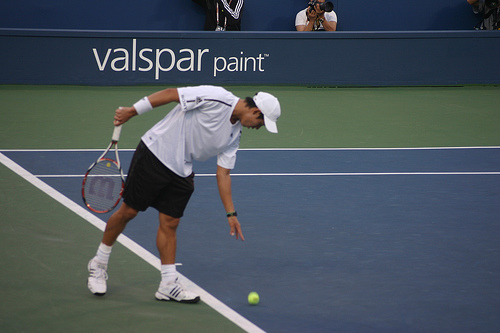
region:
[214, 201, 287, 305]
player bouncing wall on court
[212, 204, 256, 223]
black watch on player's hand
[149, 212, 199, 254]
bulges in man's foot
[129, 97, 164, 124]
white wrist band on hand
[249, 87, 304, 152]
white cap on head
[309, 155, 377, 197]
lines at side of tennis court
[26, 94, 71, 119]
green color on the pavement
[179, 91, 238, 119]
black stripe on white tee shirt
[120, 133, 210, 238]
player wearing black shorts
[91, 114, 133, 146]
white grip on tennis racket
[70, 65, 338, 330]
man bending for ball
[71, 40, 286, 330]
man holding a racket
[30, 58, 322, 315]
man wearing a cap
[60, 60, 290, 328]
man wearing a white shirt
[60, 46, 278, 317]
man wearing black shorts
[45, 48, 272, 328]
man wearing white socks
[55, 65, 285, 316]
man wearing white shoes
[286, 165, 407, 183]
white line on tennis court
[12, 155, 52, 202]
white line on tennis court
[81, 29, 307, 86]
sign in a tennis court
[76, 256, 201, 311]
THE MAN IS WEARING WHITE SHOES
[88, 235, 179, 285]
THE MAN IS WEARING WHITE SOCKS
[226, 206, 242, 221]
THE MAN IS WEARING A WATCH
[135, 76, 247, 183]
THE MAN IS WEARING A WHITE SHIRT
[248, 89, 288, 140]
THE MAN IS WEARING A WHITE HAT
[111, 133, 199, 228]
THE MAN IS WEARING BLACK SHORTS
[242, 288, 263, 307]
THE TENNIS BALL IS YELLOW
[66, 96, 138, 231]
THE MAN IS HOLDING A RACKET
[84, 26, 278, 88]
THE ADVERTISEMENT IS ON THE BLUE WALL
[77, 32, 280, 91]
THE ADVERTISEMENT READS VALSPAR PAINT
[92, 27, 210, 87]
A word "valspar" printed on the side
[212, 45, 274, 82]
A word "paint" printed on the side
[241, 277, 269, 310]
A small tennis ball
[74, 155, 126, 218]
The bottom portion of a tennis racket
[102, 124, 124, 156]
The top portion of a tennis racket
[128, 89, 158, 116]
A white wrist band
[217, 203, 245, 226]
A green wrist band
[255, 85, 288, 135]
A white cap on the helmet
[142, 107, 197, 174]
The bottom portion of a white shirt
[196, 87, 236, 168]
The top portion of a white shirt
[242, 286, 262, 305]
a yellow tennis ball on the ground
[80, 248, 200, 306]
white tennis shoes and socks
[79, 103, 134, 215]
white and red tennis racket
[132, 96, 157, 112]
white wristband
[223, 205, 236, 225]
man wearing a black watch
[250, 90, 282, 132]
a white baseball hat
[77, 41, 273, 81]
a white logo on a blue wall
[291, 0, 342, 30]
man with a camera on the side of the court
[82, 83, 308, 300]
man picking up a tennis ball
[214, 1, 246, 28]
black and white stripes